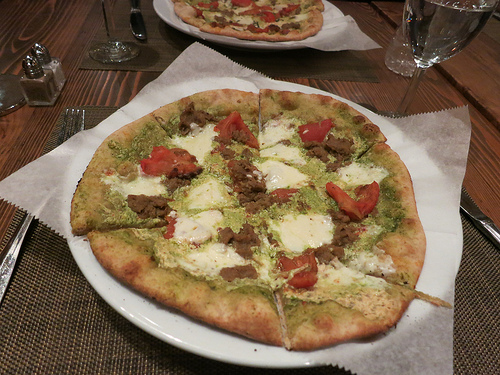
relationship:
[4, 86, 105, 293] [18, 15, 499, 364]
fork at table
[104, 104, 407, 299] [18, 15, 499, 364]
pizza on paper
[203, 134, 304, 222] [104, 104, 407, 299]
hamburger on pizza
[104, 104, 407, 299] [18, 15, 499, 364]
pizza on top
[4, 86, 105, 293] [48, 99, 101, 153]
fork has top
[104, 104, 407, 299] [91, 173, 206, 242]
pizza on sausage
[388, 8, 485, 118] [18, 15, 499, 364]
wine on table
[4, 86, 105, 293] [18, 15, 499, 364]
fork on placemet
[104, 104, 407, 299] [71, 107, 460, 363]
pizza on plate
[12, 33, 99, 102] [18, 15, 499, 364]
shaker on table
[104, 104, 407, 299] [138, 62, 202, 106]
pizza under paper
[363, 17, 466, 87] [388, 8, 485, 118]
bottle of water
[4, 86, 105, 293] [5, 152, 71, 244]
fork covered by paper